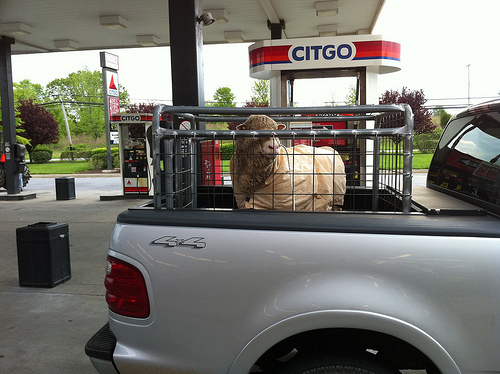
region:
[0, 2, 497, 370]
a pickup in gas station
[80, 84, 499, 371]
a sheep in a pickup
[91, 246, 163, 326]
red taillight on car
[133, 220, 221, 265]
pickup is 4x4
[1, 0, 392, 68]
roof of gas station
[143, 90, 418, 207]
sheep is in a cage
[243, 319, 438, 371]
back wheel of pickup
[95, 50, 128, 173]
a white and red board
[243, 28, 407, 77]
gas station of CITGO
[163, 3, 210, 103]
a column under a roof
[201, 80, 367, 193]
Sheep in a cage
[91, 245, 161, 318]
Light on a pickup truck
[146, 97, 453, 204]
Cage in back on truck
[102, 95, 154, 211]
Gas pump in the station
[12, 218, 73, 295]
Black trash can in station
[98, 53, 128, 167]
Price sign for gas station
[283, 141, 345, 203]
blanket over a sheep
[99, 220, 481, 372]
Gray pickup truck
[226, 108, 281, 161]
sheep looking out a cage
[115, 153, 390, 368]
Pick up truck in the gas station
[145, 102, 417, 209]
Sheep in a pen in the back of a truck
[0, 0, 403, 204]
Citgo gas station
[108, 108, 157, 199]
Gas pumps on island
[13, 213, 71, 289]
Black garbage bin on the ground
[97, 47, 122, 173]
Service station signs along side of road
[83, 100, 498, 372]
Back of silver truck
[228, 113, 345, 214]
Sheep earing plastic raincoat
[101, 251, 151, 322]
Tail light on truck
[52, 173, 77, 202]
Trash bin by gasoline island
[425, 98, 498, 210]
Rear window of truck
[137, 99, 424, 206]
A sheep in a cage.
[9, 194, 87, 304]
A garbage receptical.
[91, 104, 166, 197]
A gasoline pump.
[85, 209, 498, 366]
The fender of a 4x4.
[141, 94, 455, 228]
A clothed sheep.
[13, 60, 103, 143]
Beautifully colored trees.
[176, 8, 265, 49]
An outdoor light fixture.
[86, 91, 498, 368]
A sheep waiting on its ride.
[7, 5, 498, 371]
A truck fueling up on a dreary day.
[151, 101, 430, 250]
A sheep alone in a cage.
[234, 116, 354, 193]
large sheep in truck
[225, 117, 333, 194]
silver cage in truck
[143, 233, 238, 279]
black numbers on truck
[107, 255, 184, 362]
red light on truck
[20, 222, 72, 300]
black trash can behind truck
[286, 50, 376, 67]
blue letters on sign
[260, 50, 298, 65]
red lines on sign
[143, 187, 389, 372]
white truck by pump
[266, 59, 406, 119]
gas pump by truck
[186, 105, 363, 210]
cover over sheep in cage